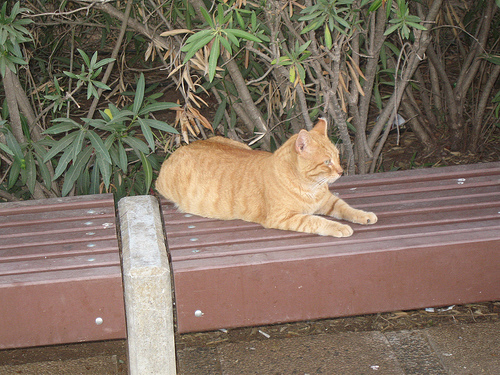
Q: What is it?
A: Cat.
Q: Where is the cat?
A: Bench.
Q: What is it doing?
A: Sitting.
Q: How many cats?
A: 1.